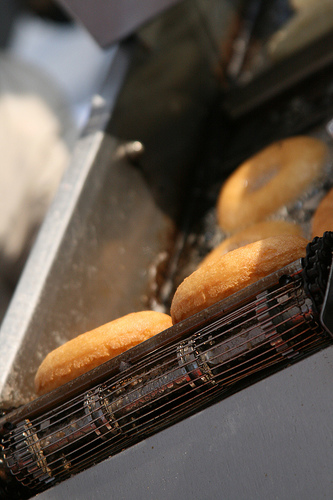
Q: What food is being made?
A: Donuts.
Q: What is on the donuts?
A: Sugar.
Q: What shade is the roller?
A: Silver.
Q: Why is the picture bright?
A: The sun.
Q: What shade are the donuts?
A: Light brown.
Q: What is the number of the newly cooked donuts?
A: Two.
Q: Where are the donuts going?
A: Down the conveyor.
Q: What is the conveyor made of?
A: Metal.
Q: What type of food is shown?
A: Doughnuts.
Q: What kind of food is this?
A: Doughnuts.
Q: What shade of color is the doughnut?
A: Golden tan.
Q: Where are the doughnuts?
A: Rotating metal conveyor.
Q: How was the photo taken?
A: At an angle.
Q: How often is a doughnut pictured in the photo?
A: Five times.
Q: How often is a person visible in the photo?
A: No people in the photo.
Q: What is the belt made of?
A: Metal.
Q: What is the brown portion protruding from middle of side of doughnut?
A: Cooked crust.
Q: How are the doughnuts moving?
A: Roller.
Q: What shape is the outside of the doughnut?
A: Round.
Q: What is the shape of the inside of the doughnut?
A: Round.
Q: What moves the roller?
A: Chain.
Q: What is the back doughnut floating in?
A: Oil.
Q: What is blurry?
A: Background.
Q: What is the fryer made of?
A: Metal.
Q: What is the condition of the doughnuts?
A: Fried.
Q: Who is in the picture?
A: Noone.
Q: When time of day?
A: Daytime.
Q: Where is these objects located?
A: Restaurant.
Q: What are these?
A: Donuts.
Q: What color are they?
A: Brown.